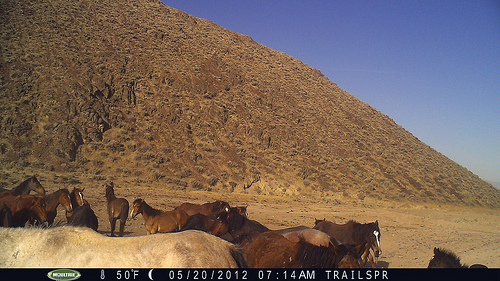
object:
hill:
[0, 0, 479, 171]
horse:
[235, 229, 338, 272]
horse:
[127, 198, 187, 232]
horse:
[100, 180, 127, 234]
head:
[99, 180, 119, 197]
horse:
[228, 229, 362, 271]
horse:
[0, 192, 47, 222]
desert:
[3, 186, 498, 265]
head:
[25, 174, 47, 198]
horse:
[0, 171, 47, 199]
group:
[1, 169, 496, 278]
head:
[22, 172, 47, 194]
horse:
[409, 240, 493, 279]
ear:
[424, 240, 452, 258]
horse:
[326, 213, 385, 256]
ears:
[369, 220, 382, 229]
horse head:
[68, 183, 96, 217]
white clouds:
[409, 92, 499, 125]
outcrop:
[43, 73, 155, 168]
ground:
[1, 185, 497, 267]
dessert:
[384, 196, 494, 251]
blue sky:
[333, 0, 498, 81]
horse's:
[245, 216, 390, 268]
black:
[304, 249, 329, 266]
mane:
[289, 244, 347, 268]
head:
[365, 215, 390, 264]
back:
[0, 222, 220, 258]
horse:
[7, 206, 259, 266]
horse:
[3, 185, 63, 229]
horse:
[177, 198, 231, 215]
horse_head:
[361, 217, 386, 258]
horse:
[184, 214, 262, 235]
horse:
[319, 209, 386, 255]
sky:
[340, 5, 490, 86]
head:
[69, 186, 89, 213]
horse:
[56, 179, 110, 231]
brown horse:
[0, 172, 48, 194]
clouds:
[427, 89, 497, 162]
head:
[207, 196, 246, 234]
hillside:
[3, 3, 496, 213]